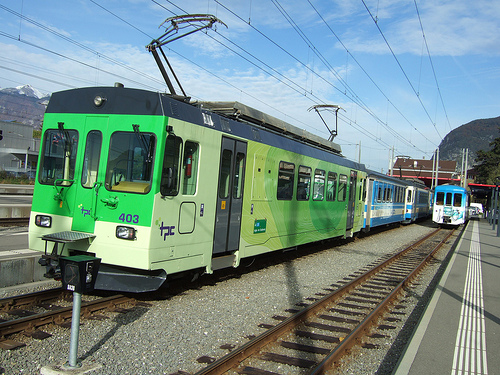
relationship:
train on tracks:
[373, 169, 473, 236] [216, 234, 442, 372]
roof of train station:
[375, 159, 495, 202] [4, 92, 498, 372]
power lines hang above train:
[0, 0, 478, 186] [424, 179, 472, 230]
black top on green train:
[52, 79, 400, 191] [28, 84, 369, 302]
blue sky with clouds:
[0, 0, 498, 196] [4, 0, 477, 169]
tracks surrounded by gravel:
[6, 224, 478, 373] [28, 219, 473, 373]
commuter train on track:
[25, 73, 435, 302] [4, 226, 479, 367]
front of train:
[31, 109, 166, 229] [25, 80, 447, 297]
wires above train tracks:
[250, 13, 391, 94] [5, 226, 456, 371]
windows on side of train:
[264, 152, 349, 210] [25, 80, 447, 297]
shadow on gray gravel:
[275, 259, 315, 370] [6, 219, 449, 368]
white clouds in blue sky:
[262, 36, 357, 103] [0, 0, 497, 94]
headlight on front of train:
[116, 226, 135, 240] [25, 80, 447, 297]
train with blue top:
[424, 179, 472, 230] [431, 178, 471, 201]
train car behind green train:
[359, 159, 446, 239] [28, 84, 369, 302]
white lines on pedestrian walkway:
[457, 210, 485, 373] [398, 216, 498, 373]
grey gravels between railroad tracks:
[115, 313, 194, 349] [6, 220, 463, 368]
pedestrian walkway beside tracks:
[398, 216, 498, 373] [6, 224, 478, 373]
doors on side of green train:
[213, 128, 242, 261] [28, 84, 369, 302]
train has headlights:
[25, 80, 447, 297] [30, 209, 140, 245]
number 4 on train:
[113, 207, 125, 225] [25, 80, 425, 297]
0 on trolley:
[121, 211, 133, 223] [21, 78, 186, 301]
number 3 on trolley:
[132, 213, 142, 225] [17, 80, 237, 301]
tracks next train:
[201, 229, 470, 372] [25, 80, 425, 297]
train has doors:
[25, 80, 425, 297] [208, 131, 255, 272]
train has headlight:
[25, 80, 425, 297] [108, 224, 140, 242]